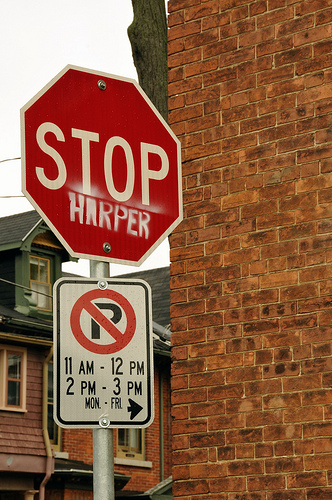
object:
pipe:
[88, 255, 115, 498]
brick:
[165, 0, 331, 498]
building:
[1, 216, 173, 498]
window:
[25, 252, 54, 308]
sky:
[33, 8, 108, 47]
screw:
[97, 79, 105, 90]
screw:
[98, 280, 107, 289]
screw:
[99, 417, 109, 426]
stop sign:
[16, 62, 190, 267]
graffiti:
[67, 192, 154, 240]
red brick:
[179, 63, 313, 302]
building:
[113, 55, 332, 494]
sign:
[52, 277, 154, 429]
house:
[10, 208, 52, 261]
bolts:
[99, 240, 117, 256]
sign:
[24, 56, 186, 268]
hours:
[66, 352, 144, 421]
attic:
[0, 205, 65, 320]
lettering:
[81, 394, 127, 411]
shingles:
[0, 217, 31, 246]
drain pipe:
[39, 343, 59, 495]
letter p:
[67, 286, 137, 354]